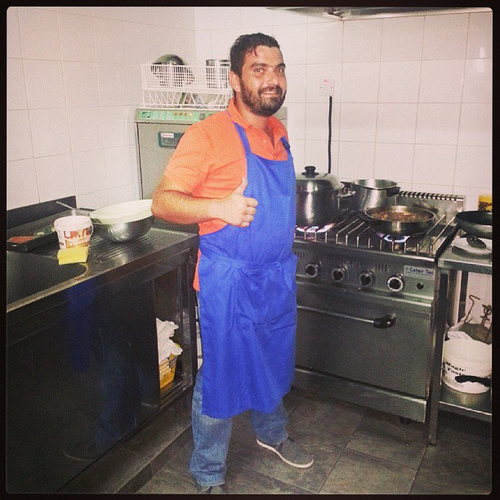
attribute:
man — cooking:
[155, 32, 315, 496]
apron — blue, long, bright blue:
[193, 121, 294, 413]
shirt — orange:
[165, 107, 288, 280]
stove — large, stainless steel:
[294, 167, 464, 435]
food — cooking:
[297, 168, 432, 231]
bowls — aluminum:
[148, 57, 230, 90]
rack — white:
[142, 62, 235, 109]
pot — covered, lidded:
[294, 165, 340, 223]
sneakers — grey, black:
[254, 435, 315, 467]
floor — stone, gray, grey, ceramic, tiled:
[133, 381, 418, 496]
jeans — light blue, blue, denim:
[195, 291, 292, 483]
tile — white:
[4, 14, 142, 198]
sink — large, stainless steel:
[7, 210, 200, 308]